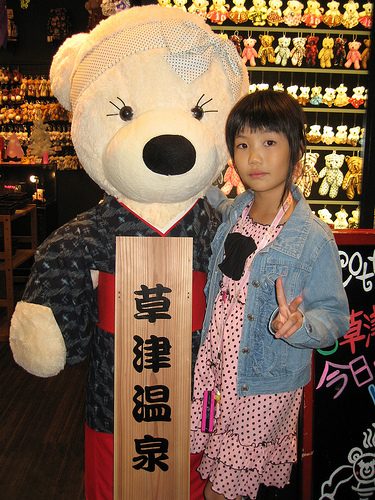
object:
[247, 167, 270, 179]
mouth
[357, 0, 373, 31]
bear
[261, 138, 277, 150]
eye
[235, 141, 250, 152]
eye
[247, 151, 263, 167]
nose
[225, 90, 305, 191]
head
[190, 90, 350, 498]
girl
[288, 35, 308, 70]
teddy bear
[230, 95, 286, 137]
bangs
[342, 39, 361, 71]
teddy bear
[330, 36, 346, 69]
teddy bear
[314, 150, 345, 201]
teddy bear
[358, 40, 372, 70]
teddy bear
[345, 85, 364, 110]
teddy bear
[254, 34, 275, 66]
teddy bear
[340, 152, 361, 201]
teddy bear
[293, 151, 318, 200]
teddy bear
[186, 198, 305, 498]
pink dress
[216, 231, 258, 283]
bow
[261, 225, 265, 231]
dots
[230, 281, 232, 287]
dots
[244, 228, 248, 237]
dots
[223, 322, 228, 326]
dots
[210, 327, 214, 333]
dots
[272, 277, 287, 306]
fingers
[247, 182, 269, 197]
chin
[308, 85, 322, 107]
teddy bear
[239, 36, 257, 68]
teddy bear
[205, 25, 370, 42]
teddy bear/shelf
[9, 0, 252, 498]
bears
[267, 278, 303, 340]
hand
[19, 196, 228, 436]
shirt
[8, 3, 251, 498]
bear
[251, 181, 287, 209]
neck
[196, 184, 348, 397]
blue jacket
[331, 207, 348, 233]
teddy bear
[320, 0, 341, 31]
bear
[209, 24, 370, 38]
shelf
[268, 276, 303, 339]
sign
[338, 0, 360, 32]
bear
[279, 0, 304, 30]
bear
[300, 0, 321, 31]
bear